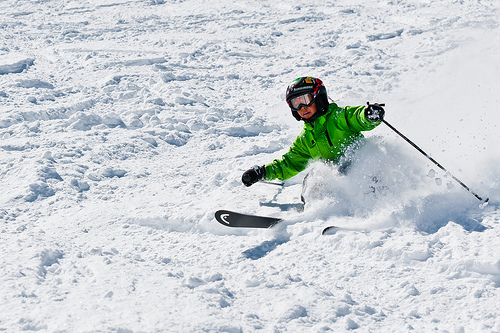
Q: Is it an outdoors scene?
A: Yes, it is outdoors.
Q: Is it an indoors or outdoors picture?
A: It is outdoors.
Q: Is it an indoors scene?
A: No, it is outdoors.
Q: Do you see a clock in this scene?
A: No, there are no clocks.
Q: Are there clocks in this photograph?
A: No, there are no clocks.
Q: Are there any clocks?
A: No, there are no clocks.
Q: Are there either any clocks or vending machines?
A: No, there are no clocks or vending machines.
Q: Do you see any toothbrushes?
A: No, there are no toothbrushes.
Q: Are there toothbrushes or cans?
A: No, there are no toothbrushes or cans.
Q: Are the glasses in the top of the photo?
A: Yes, the glasses are in the top of the image.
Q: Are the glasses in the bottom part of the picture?
A: No, the glasses are in the top of the image.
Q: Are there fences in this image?
A: No, there are no fences.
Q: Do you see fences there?
A: No, there are no fences.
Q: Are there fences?
A: No, there are no fences.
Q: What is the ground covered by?
A: The ground is covered by the snow.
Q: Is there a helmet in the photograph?
A: Yes, there is a helmet.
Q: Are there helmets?
A: Yes, there is a helmet.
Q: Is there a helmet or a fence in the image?
A: Yes, there is a helmet.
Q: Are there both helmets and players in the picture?
A: No, there is a helmet but no players.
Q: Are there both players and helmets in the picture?
A: No, there is a helmet but no players.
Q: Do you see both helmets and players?
A: No, there is a helmet but no players.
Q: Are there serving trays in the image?
A: No, there are no serving trays.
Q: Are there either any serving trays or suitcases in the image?
A: No, there are no serving trays or suitcases.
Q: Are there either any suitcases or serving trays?
A: No, there are no serving trays or suitcases.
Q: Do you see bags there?
A: No, there are no bags.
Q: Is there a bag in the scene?
A: No, there are no bags.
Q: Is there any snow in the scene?
A: Yes, there is snow.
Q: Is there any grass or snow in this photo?
A: Yes, there is snow.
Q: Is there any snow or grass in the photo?
A: Yes, there is snow.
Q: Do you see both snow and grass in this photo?
A: No, there is snow but no grass.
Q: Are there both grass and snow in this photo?
A: No, there is snow but no grass.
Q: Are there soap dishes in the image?
A: No, there are no soap dishes.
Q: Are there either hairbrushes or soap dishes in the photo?
A: No, there are no soap dishes or hairbrushes.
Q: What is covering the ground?
A: The snow is covering the ground.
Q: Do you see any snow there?
A: Yes, there is snow.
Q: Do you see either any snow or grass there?
A: Yes, there is snow.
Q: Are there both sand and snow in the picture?
A: No, there is snow but no sand.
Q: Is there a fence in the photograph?
A: No, there are no fences.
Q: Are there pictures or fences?
A: No, there are no fences or pictures.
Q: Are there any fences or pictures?
A: No, there are no fences or pictures.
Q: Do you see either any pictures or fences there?
A: No, there are no fences or pictures.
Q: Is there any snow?
A: Yes, there is snow.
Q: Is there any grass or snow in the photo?
A: Yes, there is snow.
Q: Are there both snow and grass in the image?
A: No, there is snow but no grass.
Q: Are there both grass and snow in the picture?
A: No, there is snow but no grass.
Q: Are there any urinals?
A: No, there are no urinals.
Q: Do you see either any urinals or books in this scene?
A: No, there are no urinals or books.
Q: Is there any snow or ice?
A: Yes, there is snow.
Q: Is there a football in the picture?
A: No, there are no footballs.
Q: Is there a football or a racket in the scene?
A: No, there are no footballs or rackets.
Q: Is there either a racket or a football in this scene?
A: No, there are no footballs or rackets.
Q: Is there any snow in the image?
A: Yes, there is snow.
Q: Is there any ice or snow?
A: Yes, there is snow.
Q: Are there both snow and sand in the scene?
A: No, there is snow but no sand.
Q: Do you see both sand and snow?
A: No, there is snow but no sand.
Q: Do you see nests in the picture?
A: No, there are no nests.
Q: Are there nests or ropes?
A: No, there are no nests or ropes.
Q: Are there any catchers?
A: No, there are no catchers.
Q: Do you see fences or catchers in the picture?
A: No, there are no catchers or fences.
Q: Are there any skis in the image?
A: Yes, there are skis.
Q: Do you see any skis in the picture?
A: Yes, there are skis.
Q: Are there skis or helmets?
A: Yes, there are skis.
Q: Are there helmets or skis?
A: Yes, there are skis.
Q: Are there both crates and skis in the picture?
A: No, there are skis but no crates.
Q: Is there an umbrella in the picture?
A: No, there are no umbrellas.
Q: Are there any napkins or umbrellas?
A: No, there are no umbrellas or napkins.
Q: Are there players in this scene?
A: No, there are no players.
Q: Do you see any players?
A: No, there are no players.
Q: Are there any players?
A: No, there are no players.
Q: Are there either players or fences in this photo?
A: No, there are no players or fences.